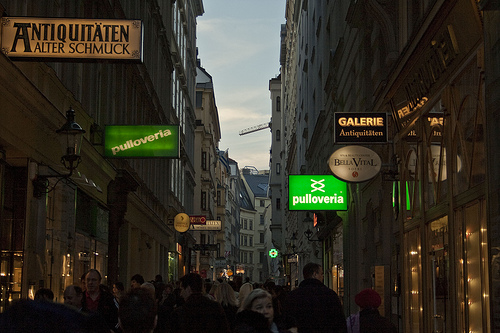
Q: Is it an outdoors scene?
A: Yes, it is outdoors.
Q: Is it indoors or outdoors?
A: It is outdoors.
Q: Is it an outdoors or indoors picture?
A: It is outdoors.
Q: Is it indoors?
A: No, it is outdoors.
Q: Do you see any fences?
A: No, there are no fences.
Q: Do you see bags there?
A: No, there are no bags.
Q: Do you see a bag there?
A: No, there are no bags.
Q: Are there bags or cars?
A: No, there are no bags or cars.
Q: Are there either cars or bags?
A: No, there are no bags or cars.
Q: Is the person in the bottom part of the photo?
A: Yes, the person is in the bottom of the image.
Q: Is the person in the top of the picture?
A: No, the person is in the bottom of the image.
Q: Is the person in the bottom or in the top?
A: The person is in the bottom of the image.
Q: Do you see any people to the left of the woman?
A: Yes, there is a person to the left of the woman.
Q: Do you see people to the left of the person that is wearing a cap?
A: Yes, there is a person to the left of the woman.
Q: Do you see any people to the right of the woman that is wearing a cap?
A: No, the person is to the left of the woman.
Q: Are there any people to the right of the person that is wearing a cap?
A: No, the person is to the left of the woman.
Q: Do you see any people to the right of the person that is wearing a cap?
A: No, the person is to the left of the woman.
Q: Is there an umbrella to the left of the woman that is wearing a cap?
A: No, there is a person to the left of the woman.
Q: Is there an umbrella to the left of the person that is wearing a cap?
A: No, there is a person to the left of the woman.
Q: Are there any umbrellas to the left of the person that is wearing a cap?
A: No, there is a person to the left of the woman.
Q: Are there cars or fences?
A: No, there are no fences or cars.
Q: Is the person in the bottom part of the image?
A: Yes, the person is in the bottom of the image.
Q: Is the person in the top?
A: No, the person is in the bottom of the image.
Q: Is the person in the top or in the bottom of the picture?
A: The person is in the bottom of the image.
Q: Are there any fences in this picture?
A: No, there are no fences.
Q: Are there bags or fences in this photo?
A: No, there are no fences or bags.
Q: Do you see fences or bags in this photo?
A: No, there are no fences or bags.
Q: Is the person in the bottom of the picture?
A: Yes, the person is in the bottom of the image.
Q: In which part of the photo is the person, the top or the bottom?
A: The person is in the bottom of the image.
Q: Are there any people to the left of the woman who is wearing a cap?
A: Yes, there is a person to the left of the woman.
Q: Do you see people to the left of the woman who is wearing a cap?
A: Yes, there is a person to the left of the woman.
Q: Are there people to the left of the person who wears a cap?
A: Yes, there is a person to the left of the woman.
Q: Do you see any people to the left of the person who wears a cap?
A: Yes, there is a person to the left of the woman.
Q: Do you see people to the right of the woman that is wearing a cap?
A: No, the person is to the left of the woman.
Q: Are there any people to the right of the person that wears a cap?
A: No, the person is to the left of the woman.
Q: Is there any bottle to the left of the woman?
A: No, there is a person to the left of the woman.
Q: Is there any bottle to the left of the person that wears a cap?
A: No, there is a person to the left of the woman.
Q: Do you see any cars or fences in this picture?
A: No, there are no fences or cars.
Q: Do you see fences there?
A: No, there are no fences.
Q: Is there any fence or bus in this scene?
A: No, there are no fences or buses.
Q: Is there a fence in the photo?
A: No, there are no fences.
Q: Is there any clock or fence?
A: No, there are no fences or clocks.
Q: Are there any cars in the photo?
A: No, there are no cars.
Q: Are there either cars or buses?
A: No, there are no cars or buses.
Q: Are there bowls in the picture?
A: No, there are no bowls.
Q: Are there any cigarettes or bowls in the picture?
A: No, there are no bowls or cigarettes.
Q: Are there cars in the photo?
A: No, there are no cars.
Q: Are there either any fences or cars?
A: No, there are no cars or fences.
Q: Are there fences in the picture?
A: No, there are no fences.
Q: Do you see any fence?
A: No, there are no fences.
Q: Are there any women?
A: Yes, there is a woman.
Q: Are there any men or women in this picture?
A: Yes, there is a woman.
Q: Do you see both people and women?
A: Yes, there are both a woman and a person.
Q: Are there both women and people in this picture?
A: Yes, there are both a woman and a person.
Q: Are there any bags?
A: No, there are no bags.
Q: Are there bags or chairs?
A: No, there are no bags or chairs.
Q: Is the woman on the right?
A: Yes, the woman is on the right of the image.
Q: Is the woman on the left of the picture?
A: No, the woman is on the right of the image.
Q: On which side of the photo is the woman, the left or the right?
A: The woman is on the right of the image.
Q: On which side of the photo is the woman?
A: The woman is on the right of the image.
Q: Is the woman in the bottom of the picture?
A: Yes, the woman is in the bottom of the image.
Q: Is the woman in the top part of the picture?
A: No, the woman is in the bottom of the image.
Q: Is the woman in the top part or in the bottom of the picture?
A: The woman is in the bottom of the image.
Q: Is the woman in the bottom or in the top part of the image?
A: The woman is in the bottom of the image.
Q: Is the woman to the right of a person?
A: Yes, the woman is to the right of a person.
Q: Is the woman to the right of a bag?
A: No, the woman is to the right of a person.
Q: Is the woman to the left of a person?
A: No, the woman is to the right of a person.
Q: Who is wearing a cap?
A: The woman is wearing a cap.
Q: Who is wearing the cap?
A: The woman is wearing a cap.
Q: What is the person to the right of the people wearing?
A: The woman is wearing a cap.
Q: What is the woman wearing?
A: The woman is wearing a cap.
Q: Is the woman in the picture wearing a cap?
A: Yes, the woman is wearing a cap.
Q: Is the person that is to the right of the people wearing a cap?
A: Yes, the woman is wearing a cap.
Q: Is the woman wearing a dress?
A: No, the woman is wearing a cap.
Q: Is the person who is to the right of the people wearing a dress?
A: No, the woman is wearing a cap.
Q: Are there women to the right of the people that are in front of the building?
A: Yes, there is a woman to the right of the people.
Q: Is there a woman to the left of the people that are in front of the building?
A: No, the woman is to the right of the people.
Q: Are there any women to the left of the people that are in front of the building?
A: No, the woman is to the right of the people.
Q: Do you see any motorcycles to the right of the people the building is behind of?
A: No, there is a woman to the right of the people.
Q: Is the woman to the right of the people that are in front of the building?
A: Yes, the woman is to the right of the people.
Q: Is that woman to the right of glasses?
A: No, the woman is to the right of the people.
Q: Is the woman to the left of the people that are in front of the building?
A: No, the woman is to the right of the people.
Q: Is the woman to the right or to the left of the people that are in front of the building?
A: The woman is to the right of the people.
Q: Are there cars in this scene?
A: No, there are no cars.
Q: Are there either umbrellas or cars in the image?
A: No, there are no cars or umbrellas.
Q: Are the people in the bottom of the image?
A: Yes, the people are in the bottom of the image.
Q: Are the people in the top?
A: No, the people are in the bottom of the image.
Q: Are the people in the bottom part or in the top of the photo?
A: The people are in the bottom of the image.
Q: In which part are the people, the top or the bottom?
A: The people are in the bottom of the image.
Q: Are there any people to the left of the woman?
A: Yes, there are people to the left of the woman.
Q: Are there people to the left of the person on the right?
A: Yes, there are people to the left of the woman.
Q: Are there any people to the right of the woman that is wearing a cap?
A: No, the people are to the left of the woman.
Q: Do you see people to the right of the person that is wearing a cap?
A: No, the people are to the left of the woman.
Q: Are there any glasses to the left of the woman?
A: No, there are people to the left of the woman.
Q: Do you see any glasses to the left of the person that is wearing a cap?
A: No, there are people to the left of the woman.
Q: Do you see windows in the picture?
A: Yes, there is a window.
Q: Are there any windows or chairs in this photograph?
A: Yes, there is a window.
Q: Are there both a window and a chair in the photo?
A: No, there is a window but no chairs.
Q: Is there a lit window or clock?
A: Yes, there is a lit window.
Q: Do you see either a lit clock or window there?
A: Yes, there is a lit window.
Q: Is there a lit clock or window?
A: Yes, there is a lit window.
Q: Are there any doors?
A: No, there are no doors.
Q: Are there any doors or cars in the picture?
A: No, there are no doors or cars.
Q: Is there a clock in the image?
A: No, there are no clocks.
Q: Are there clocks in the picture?
A: No, there are no clocks.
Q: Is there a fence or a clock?
A: No, there are no clocks or fences.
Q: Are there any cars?
A: No, there are no cars.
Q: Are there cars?
A: No, there are no cars.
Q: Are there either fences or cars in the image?
A: No, there are no cars or fences.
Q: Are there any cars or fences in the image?
A: No, there are no cars or fences.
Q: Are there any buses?
A: No, there are no buses.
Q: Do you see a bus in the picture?
A: No, there are no buses.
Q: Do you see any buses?
A: No, there are no buses.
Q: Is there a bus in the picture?
A: No, there are no buses.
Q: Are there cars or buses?
A: No, there are no buses or cars.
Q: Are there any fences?
A: No, there are no fences.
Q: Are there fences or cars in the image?
A: No, there are no fences or cars.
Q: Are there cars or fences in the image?
A: No, there are no fences or cars.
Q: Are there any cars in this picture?
A: No, there are no cars.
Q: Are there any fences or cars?
A: No, there are no cars or fences.